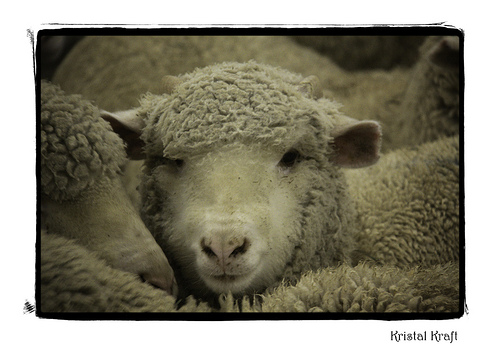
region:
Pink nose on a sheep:
[203, 231, 256, 261]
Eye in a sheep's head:
[274, 145, 314, 166]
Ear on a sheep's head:
[322, 111, 381, 162]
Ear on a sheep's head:
[99, 108, 147, 155]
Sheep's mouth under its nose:
[206, 268, 253, 287]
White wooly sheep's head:
[150, 61, 325, 157]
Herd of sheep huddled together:
[40, 35, 460, 310]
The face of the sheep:
[158, 122, 314, 274]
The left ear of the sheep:
[97, 102, 147, 142]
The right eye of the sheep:
[277, 130, 322, 180]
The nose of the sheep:
[196, 226, 249, 254]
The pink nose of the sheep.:
[185, 220, 245, 255]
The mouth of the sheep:
[195, 261, 270, 304]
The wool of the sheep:
[333, 132, 465, 263]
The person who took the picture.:
[388, 322, 459, 346]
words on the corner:
[381, 319, 461, 346]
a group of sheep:
[40, 35, 464, 319]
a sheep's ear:
[322, 89, 420, 185]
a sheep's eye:
[270, 137, 319, 182]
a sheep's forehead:
[188, 85, 283, 145]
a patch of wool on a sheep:
[401, 190, 443, 220]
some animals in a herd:
[47, 36, 467, 318]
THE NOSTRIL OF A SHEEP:
[227, 237, 249, 259]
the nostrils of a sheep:
[198, 240, 250, 260]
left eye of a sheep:
[277, 149, 302, 168]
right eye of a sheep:
[162, 153, 189, 170]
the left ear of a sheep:
[327, 117, 382, 167]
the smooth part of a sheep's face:
[157, 143, 307, 289]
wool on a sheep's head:
[142, 63, 338, 153]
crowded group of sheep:
[37, 34, 458, 314]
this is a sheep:
[101, 50, 444, 328]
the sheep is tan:
[131, 43, 456, 312]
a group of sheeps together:
[52, 35, 464, 317]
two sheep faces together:
[41, 69, 376, 308]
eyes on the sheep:
[131, 118, 324, 190]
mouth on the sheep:
[201, 260, 257, 297]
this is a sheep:
[47, 54, 425, 304]